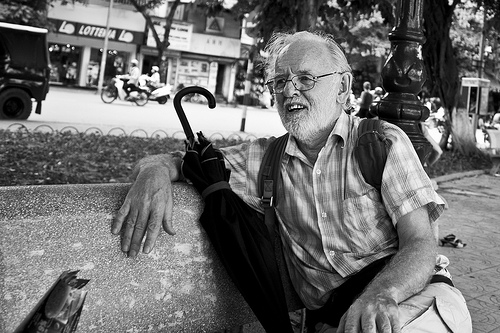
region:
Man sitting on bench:
[111, 29, 473, 331]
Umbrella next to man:
[172, 85, 297, 332]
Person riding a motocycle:
[98, 58, 150, 107]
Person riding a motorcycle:
[138, 65, 173, 106]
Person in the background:
[355, 81, 374, 118]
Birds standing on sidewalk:
[437, 232, 466, 249]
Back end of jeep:
[1, 20, 50, 123]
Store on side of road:
[47, 4, 147, 93]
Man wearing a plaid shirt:
[108, 31, 471, 331]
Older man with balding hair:
[109, 27, 471, 332]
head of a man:
[238, 18, 388, 144]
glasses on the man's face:
[243, 57, 327, 105]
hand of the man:
[83, 157, 190, 266]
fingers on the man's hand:
[97, 200, 177, 266]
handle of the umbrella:
[142, 72, 234, 145]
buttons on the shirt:
[276, 134, 391, 279]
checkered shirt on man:
[251, 128, 406, 260]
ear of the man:
[316, 64, 360, 119]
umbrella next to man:
[158, 124, 317, 321]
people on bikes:
[79, 60, 173, 125]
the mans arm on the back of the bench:
[111, 133, 184, 261]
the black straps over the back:
[255, 116, 387, 241]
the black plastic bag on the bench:
[15, 268, 96, 332]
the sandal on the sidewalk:
[441, 230, 467, 251]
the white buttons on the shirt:
[314, 167, 339, 262]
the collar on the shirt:
[328, 108, 352, 146]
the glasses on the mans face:
[262, 70, 347, 90]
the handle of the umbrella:
[170, 83, 219, 149]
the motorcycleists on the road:
[99, 58, 173, 111]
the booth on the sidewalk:
[461, 73, 488, 124]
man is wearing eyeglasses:
[255, 52, 337, 127]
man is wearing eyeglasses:
[246, 62, 326, 107]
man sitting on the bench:
[143, 22, 459, 326]